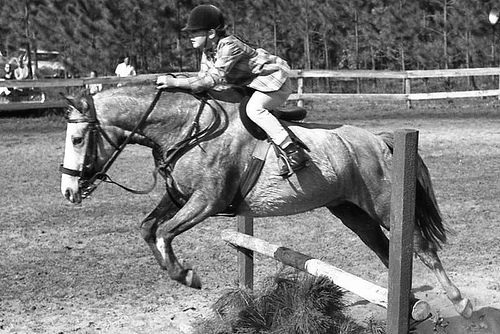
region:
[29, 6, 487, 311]
black and white photo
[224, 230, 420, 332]
bush on top of wooden pole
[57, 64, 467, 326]
horse jumping over wood structure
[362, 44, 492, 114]
wooden fencing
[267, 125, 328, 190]
black boot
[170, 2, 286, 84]
girl with black hard hat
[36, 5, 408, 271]
girl riding horse that is jumping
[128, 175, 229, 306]
horse legs in montion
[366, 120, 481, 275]
dark horse tail near wood pole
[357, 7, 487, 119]
forest behind wooden fence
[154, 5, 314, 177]
young girl on a horse's back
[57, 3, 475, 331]
young female jockey riding a horse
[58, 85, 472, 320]
horse jumping over a wooden pole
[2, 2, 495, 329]
girl practicing riding a horse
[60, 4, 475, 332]
girl jockey riding a horse in a fenced area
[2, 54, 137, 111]
four people watching the young jockey ride a horse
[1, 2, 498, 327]
picture of a young girl riding a horse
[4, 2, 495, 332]
people at a horse ranch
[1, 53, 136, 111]
people standing behind a wooden fence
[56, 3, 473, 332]
horse jumping over a pole with a girl on the back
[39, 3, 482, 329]
young girl riding a horse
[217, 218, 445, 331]
fence horse is jumping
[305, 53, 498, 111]
fence behind the jumping horse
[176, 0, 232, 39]
helmet on rider's head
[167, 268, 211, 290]
left hoof of a horse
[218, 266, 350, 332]
grasses below fence horse is jumping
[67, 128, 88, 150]
left eye of a horse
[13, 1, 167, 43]
trees lines behind the fence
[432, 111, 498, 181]
dirt ground where horse is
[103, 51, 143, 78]
man watching in the background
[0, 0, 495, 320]
the picture is in black and white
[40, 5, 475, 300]
the horse is jumping over the stick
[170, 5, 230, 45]
the girl is wearing a helmet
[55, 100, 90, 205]
the horse's face is white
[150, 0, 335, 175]
the girl is holding on to the straps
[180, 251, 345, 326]
a tumble weed is in front of the stick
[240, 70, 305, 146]
the girl's pants are white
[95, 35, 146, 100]
a person is watching the child on the horse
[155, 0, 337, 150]
the girl is leaning forward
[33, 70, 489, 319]
the horse is in the air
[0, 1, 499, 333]
The scene is shot in black and white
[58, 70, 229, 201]
the horses reins are black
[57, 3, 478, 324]
Horse and rider are jumping the first gate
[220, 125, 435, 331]
The hurdle is made of wood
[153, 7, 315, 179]
The rider is called a jockey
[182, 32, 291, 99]
The jacket is checkered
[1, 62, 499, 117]
Wood fence is in the background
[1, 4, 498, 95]
Trees are behind the fence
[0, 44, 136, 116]
People watch from the fence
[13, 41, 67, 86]
The car is behind the tree